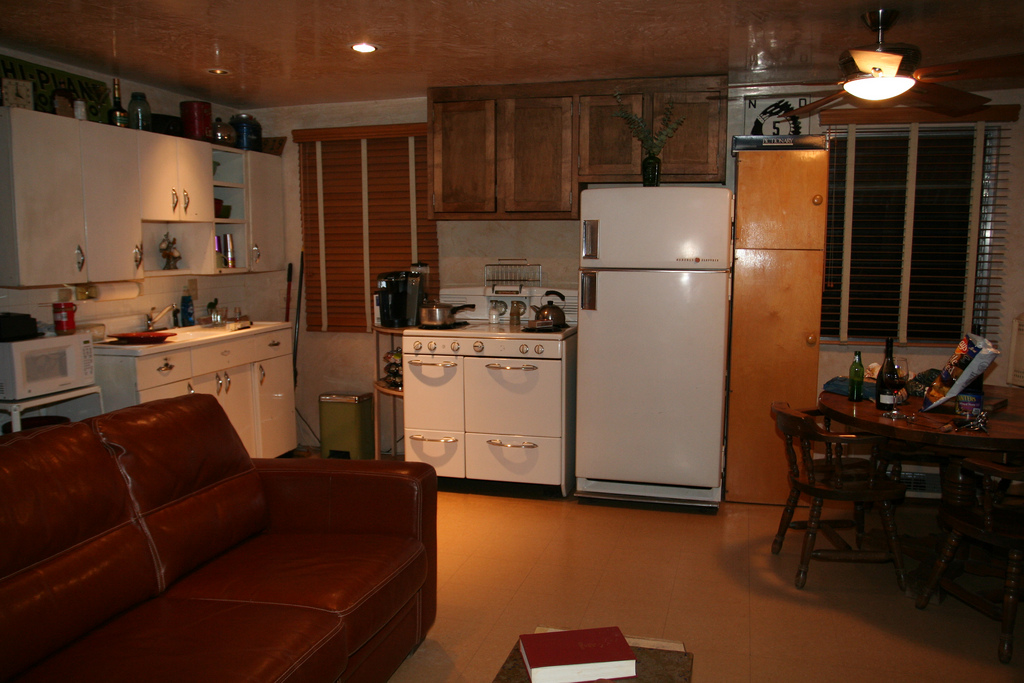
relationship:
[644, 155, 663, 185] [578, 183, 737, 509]
vase on fridge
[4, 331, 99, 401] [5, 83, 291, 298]
microwave under cabinet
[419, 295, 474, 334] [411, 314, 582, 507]
pot on stove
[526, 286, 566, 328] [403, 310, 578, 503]
kettle on stove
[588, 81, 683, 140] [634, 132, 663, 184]
plant in vase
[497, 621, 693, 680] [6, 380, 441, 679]
table in front of couch